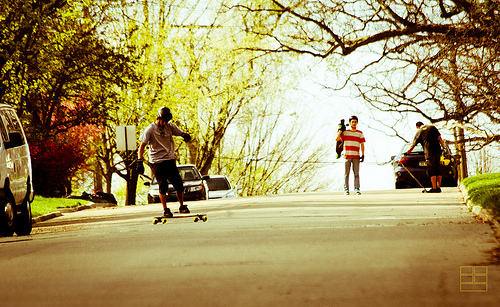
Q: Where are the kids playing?
A: Street.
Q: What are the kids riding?
A: Skateboards.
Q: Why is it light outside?
A: Sun.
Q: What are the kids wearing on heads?
A: Helmets.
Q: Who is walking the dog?
A: Nobody.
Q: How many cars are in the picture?
A: 4.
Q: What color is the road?
A: Grey.